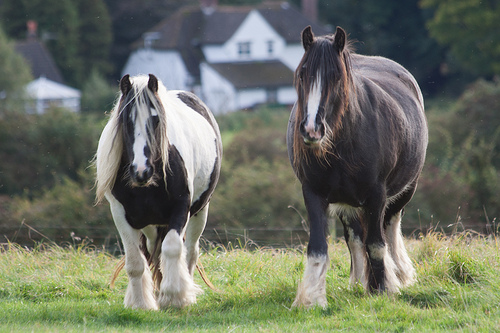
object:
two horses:
[87, 25, 429, 314]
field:
[3, 24, 495, 330]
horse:
[287, 25, 429, 311]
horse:
[84, 72, 223, 310]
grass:
[1, 224, 500, 333]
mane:
[291, 40, 347, 158]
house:
[121, 4, 341, 115]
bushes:
[0, 76, 498, 247]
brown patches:
[111, 142, 191, 236]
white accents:
[303, 71, 322, 131]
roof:
[132, 5, 331, 49]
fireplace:
[301, 0, 318, 28]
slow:
[287, 181, 417, 317]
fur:
[90, 73, 222, 311]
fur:
[290, 208, 417, 313]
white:
[95, 74, 202, 316]